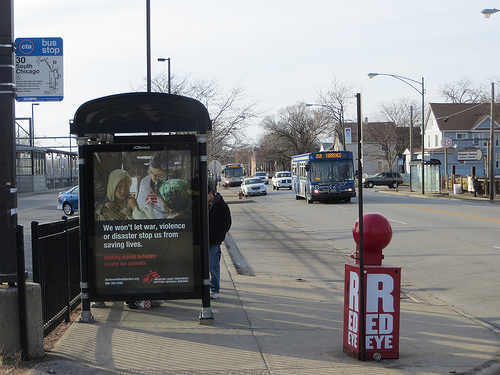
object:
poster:
[92, 149, 194, 295]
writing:
[102, 222, 189, 286]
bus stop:
[408, 158, 442, 193]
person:
[207, 176, 233, 299]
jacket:
[209, 192, 233, 246]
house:
[318, 121, 421, 183]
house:
[251, 146, 291, 176]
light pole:
[367, 72, 427, 195]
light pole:
[156, 57, 170, 94]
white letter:
[348, 270, 360, 312]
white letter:
[365, 335, 374, 349]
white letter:
[348, 310, 359, 333]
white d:
[377, 313, 393, 335]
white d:
[111, 233, 115, 240]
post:
[342, 212, 402, 362]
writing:
[347, 331, 359, 349]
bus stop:
[67, 91, 215, 326]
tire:
[63, 201, 74, 216]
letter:
[384, 334, 394, 349]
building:
[402, 101, 498, 189]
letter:
[365, 313, 379, 335]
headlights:
[347, 188, 352, 192]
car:
[240, 177, 267, 197]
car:
[271, 171, 292, 191]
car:
[252, 171, 269, 185]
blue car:
[56, 185, 78, 215]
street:
[403, 213, 499, 338]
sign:
[13, 36, 64, 102]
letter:
[365, 273, 396, 313]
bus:
[290, 150, 357, 204]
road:
[217, 149, 500, 375]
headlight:
[313, 189, 320, 194]